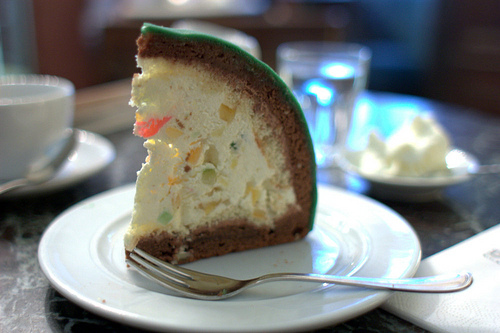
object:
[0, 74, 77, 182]
cup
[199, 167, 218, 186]
fruit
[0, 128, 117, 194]
plate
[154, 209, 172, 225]
fruit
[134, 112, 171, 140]
candy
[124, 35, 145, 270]
edge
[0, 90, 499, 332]
table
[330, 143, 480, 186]
round plate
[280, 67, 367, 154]
water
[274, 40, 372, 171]
glass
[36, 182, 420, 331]
plate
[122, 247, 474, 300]
fork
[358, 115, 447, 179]
icing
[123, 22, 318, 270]
cake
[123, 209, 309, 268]
layer